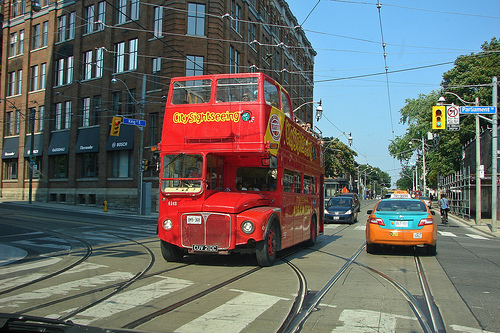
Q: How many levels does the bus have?
A: Two.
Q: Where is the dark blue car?
A: Behind the bus.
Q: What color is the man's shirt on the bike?
A: Blue.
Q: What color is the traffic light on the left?
A: Red.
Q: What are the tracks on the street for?
A: Trolleys.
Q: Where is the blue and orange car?
A: Beneath the green light.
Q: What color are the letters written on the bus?
A: Yellow.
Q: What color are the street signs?
A: Blue.